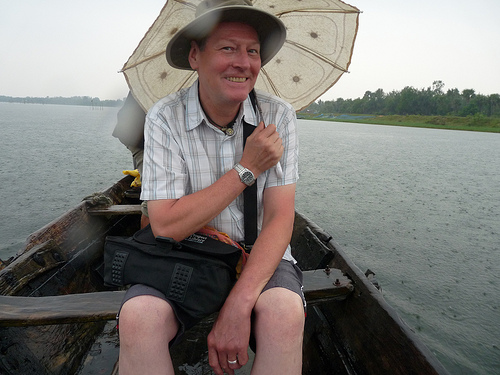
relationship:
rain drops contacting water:
[399, 273, 416, 304] [5, 88, 489, 360]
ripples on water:
[423, 184, 476, 312] [0, 99, 498, 372]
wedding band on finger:
[226, 357, 236, 367] [228, 349, 239, 374]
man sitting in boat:
[115, 0, 305, 373] [0, 154, 451, 374]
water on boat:
[78, 315, 118, 374] [0, 154, 451, 374]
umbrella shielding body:
[116, 0, 365, 180] [115, 23, 304, 371]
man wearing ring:
[115, 0, 305, 373] [226, 357, 236, 364]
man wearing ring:
[115, 0, 305, 373] [226, 357, 238, 367]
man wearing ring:
[115, 0, 305, 373] [217, 345, 249, 367]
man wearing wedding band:
[115, 0, 305, 373] [226, 358, 235, 367]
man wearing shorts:
[115, 0, 305, 373] [116, 245, 311, 313]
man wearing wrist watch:
[115, 0, 305, 373] [233, 162, 255, 188]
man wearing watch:
[115, 0, 305, 373] [232, 162, 256, 188]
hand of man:
[206, 316, 250, 373] [115, 0, 305, 373]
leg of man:
[110, 278, 184, 373] [115, 0, 305, 373]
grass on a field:
[300, 109, 498, 135] [311, 110, 499, 130]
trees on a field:
[352, 86, 497, 114] [311, 110, 499, 130]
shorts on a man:
[273, 259, 305, 302] [115, 0, 305, 373]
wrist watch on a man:
[233, 162, 255, 184] [229, 160, 264, 187]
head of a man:
[176, 1, 266, 106] [115, 0, 305, 373]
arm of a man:
[218, 103, 298, 318] [115, 0, 305, 373]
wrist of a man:
[221, 277, 262, 327] [115, 0, 305, 373]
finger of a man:
[247, 105, 304, 190] [115, 0, 305, 373]